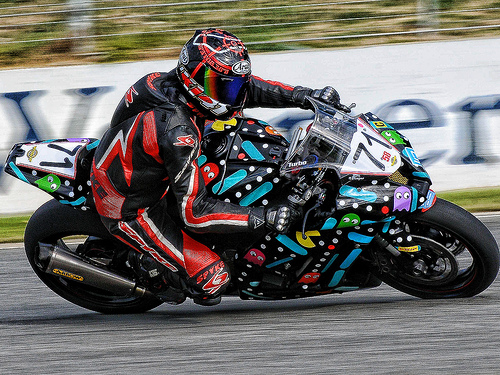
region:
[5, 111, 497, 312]
A PacMan themed motorcycle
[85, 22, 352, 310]
a motorcyclist wearing a black and red outfit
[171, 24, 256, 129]
a motorcyclist wearing a helmet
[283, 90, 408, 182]
windshield of motorcycle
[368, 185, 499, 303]
front wheel of motorcycle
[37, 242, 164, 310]
exhaust pipe on motorcycle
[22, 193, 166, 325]
back wheel of motorcycle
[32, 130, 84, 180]
number of motorcycle written on back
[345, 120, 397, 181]
number of motorcycle written on front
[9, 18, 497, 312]
motocyclist riding a motorcycle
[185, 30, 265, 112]
Person wearing dark helmet.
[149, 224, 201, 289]
Person wearing red and black pants.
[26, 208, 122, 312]
Bike has black back tire.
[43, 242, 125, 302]
Silver exhaust on back of bike.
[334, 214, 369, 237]
Green pac man ghost on bike.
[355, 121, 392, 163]
Black numbers on front of bike.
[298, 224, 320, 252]
Yellow pac man on side of bike.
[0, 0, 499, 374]
A motorcyclist is riding his motorcycle.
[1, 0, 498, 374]
The motorcycle is very fast.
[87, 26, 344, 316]
The motorcyclist is wearing red and black.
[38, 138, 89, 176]
The motorcycle number is 71.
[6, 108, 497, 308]
The motorcycle is black and blue.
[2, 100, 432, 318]
The motorcycle is decorated with Pac-Man art.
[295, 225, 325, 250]
Pac-Man is on the motorcycle.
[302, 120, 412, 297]
Colorful ghosts are on the motorcycle.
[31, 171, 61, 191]
The ghost is green.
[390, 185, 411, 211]
The ghost is purple.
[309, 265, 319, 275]
white dot on motorcycle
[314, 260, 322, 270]
white dot on motorcycle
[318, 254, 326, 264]
white dot on motorcycle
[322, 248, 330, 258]
white dot on motorcycle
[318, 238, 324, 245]
white dot on motorcycle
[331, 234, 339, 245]
white dot on motorcycle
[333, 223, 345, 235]
white dot on motorcycle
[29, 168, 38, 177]
white dot on motorcycle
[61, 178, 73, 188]
white dot on motorcycle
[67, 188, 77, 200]
white dot on motorcycle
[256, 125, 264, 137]
white dot on motorcycle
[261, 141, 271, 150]
white dot on motorcycle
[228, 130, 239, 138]
white dot on motorcycle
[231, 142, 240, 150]
white dot on motorcycle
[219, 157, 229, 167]
white dot on motorcycle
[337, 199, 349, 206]
white dot on motorcycle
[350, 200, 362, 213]
white dot on motorcycle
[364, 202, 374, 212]
white dot on motorcycle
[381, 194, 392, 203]
white dot on motorcycle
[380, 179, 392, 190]
white dot on motorcycle